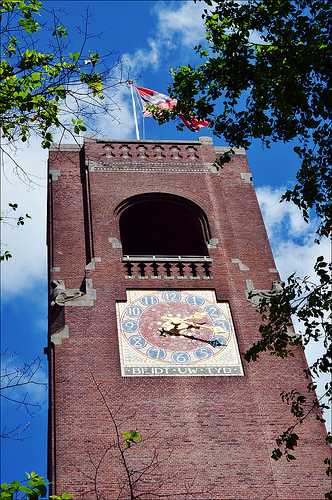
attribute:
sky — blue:
[122, 12, 185, 83]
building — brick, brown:
[130, 149, 228, 291]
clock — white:
[117, 280, 242, 396]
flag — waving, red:
[117, 67, 189, 146]